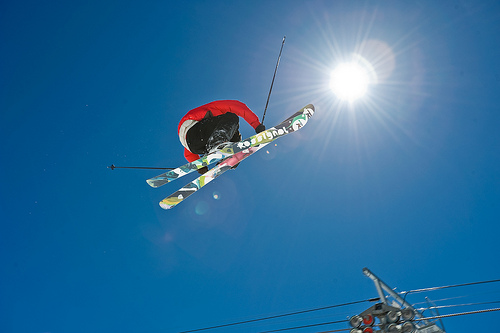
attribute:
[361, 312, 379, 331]
wheels — orange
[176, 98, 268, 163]
jacket — orange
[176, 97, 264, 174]
skier — jumping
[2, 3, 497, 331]
sky — blue, clear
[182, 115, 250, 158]
pants — black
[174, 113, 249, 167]
pants — black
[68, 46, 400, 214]
person — multicolor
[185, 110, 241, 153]
pants — black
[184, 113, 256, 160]
pants — black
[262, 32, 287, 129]
ski pole — black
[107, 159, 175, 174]
ski pole — black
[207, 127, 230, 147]
shoe — black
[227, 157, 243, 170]
shoe — black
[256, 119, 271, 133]
glove — black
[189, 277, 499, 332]
wires — metal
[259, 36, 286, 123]
ski pole — black, white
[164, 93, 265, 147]
coat — red